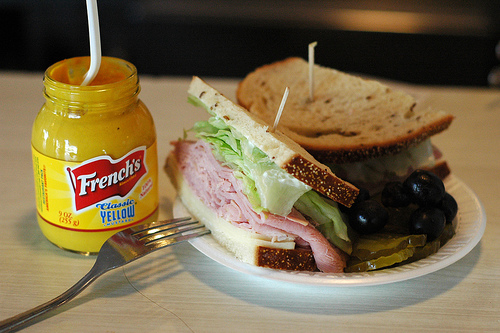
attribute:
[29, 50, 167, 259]
mustard jar — glass, french's, uncovered, open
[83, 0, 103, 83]
utensil — plastic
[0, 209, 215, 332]
fork — silver, metal, shiny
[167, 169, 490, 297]
plate — white, silver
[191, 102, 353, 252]
lettuce — thick, crispy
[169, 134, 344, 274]
meat — pink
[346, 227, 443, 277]
pickles — green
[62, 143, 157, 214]
logo — red, red flag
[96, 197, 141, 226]
classic yellow — blue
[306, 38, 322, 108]
toothpick — wooden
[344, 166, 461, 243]
black olives — round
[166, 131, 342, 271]
ham — sliced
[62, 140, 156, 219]
flag — red